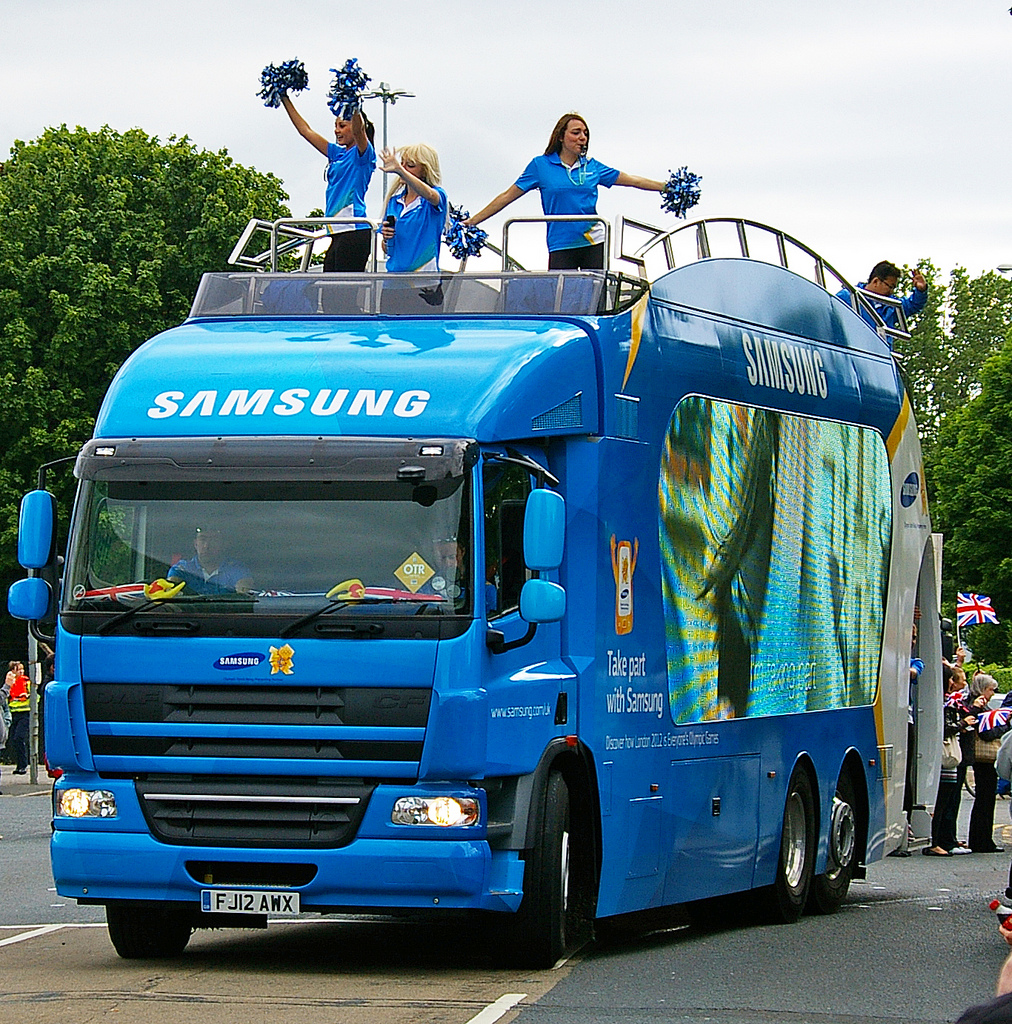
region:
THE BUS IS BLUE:
[57, 185, 959, 952]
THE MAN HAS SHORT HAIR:
[870, 258, 903, 294]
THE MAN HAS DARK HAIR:
[857, 258, 904, 284]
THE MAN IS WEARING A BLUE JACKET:
[834, 273, 935, 340]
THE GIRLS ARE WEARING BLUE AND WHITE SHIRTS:
[260, 96, 666, 282]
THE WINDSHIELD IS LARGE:
[31, 414, 493, 671]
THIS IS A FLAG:
[941, 565, 1007, 648]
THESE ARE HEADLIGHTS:
[14, 760, 520, 865]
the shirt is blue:
[516, 156, 621, 229]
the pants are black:
[545, 243, 607, 274]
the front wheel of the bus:
[506, 774, 610, 941]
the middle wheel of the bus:
[778, 779, 824, 913]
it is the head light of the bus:
[379, 782, 488, 842]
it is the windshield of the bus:
[74, 458, 483, 621]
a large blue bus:
[57, 223, 949, 934]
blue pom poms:
[247, 56, 387, 126]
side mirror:
[512, 477, 579, 644]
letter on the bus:
[383, 379, 426, 429]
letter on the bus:
[346, 398, 395, 422]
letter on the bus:
[144, 380, 171, 420]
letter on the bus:
[187, 386, 208, 420]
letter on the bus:
[237, 385, 270, 422]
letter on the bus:
[740, 335, 767, 387]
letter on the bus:
[811, 348, 841, 397]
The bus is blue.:
[36, 234, 965, 965]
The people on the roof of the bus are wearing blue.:
[265, 55, 927, 326]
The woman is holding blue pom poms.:
[259, 39, 380, 260]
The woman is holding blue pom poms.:
[437, 106, 695, 273]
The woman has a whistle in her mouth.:
[463, 107, 697, 270]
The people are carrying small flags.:
[940, 583, 1009, 857]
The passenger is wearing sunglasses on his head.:
[152, 503, 258, 602]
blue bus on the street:
[25, 251, 931, 942]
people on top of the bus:
[236, 60, 934, 334]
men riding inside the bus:
[162, 509, 481, 604]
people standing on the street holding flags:
[940, 566, 1010, 832]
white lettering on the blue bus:
[140, 374, 437, 428]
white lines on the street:
[4, 895, 520, 1023]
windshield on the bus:
[75, 459, 455, 618]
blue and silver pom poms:
[270, 46, 719, 262]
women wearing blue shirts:
[270, 73, 666, 275]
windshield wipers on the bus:
[94, 574, 373, 649]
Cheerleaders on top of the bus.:
[233, 35, 682, 283]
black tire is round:
[505, 774, 572, 967]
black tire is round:
[764, 765, 820, 921]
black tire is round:
[812, 790, 859, 915]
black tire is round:
[105, 904, 197, 960]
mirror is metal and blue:
[523, 491, 569, 573]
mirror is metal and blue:
[518, 577, 570, 621]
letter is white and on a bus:
[397, 385, 430, 419]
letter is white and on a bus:
[349, 389, 390, 413]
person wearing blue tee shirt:
[470, 112, 679, 275]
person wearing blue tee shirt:
[264, 67, 381, 269]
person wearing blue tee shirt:
[373, 141, 451, 274]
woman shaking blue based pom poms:
[455, 110, 705, 286]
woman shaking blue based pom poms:
[256, 50, 375, 271]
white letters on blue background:
[145, 382, 431, 425]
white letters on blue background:
[736, 323, 834, 403]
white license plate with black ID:
[200, 881, 302, 914]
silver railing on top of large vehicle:
[607, 212, 916, 356]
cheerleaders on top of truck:
[208, 33, 832, 303]